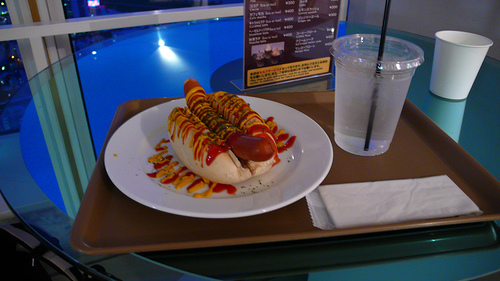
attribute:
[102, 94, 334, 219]
plate — round, white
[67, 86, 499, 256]
tray — plastic, brown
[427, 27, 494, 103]
cup — white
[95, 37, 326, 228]
plate — white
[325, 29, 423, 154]
plastic cup — clear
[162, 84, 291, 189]
food — brown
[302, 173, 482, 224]
napkin — paper, rectangular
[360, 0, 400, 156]
straw — black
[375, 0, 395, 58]
black straw — plastic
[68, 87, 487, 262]
tabletop — round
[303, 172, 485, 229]
napkin — white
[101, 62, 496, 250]
table — glass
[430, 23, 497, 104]
cup — paper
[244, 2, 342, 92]
lettering — white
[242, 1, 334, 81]
menu — brown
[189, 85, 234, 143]
mustard — drizzle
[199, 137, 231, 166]
ketchup — drizzle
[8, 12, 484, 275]
table — glass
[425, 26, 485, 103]
cup — paper, white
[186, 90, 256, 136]
mustard — bright yellow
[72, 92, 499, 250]
serving try — rectangular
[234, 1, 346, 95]
holder — plastic, vertical